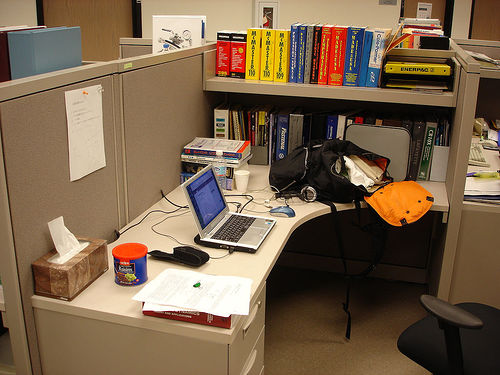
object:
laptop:
[180, 162, 277, 255]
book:
[327, 23, 348, 86]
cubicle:
[0, 42, 481, 375]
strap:
[319, 199, 353, 340]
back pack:
[268, 137, 436, 342]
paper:
[131, 266, 252, 317]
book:
[141, 301, 238, 330]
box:
[29, 235, 108, 305]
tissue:
[45, 216, 80, 260]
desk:
[31, 165, 451, 374]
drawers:
[235, 325, 266, 374]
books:
[245, 27, 261, 81]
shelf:
[204, 75, 457, 109]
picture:
[261, 4, 274, 28]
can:
[111, 240, 148, 286]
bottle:
[210, 147, 230, 196]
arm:
[418, 293, 483, 330]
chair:
[396, 292, 500, 375]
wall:
[0, 0, 38, 34]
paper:
[64, 83, 108, 184]